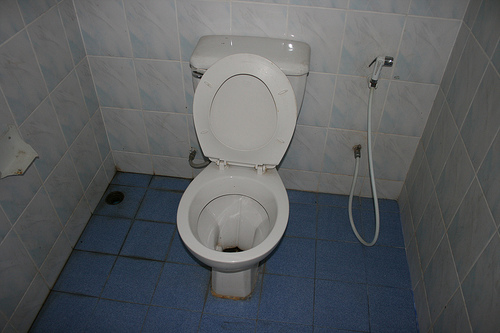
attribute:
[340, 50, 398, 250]
hose — white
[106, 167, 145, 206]
spot — brown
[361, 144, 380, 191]
ground — blue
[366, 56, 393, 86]
spray nozzle — white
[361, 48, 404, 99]
handle — black, a faucet handle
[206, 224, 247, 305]
spot — brown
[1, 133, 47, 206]
dispenser — broken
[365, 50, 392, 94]
faucet handle — black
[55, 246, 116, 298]
tile — blue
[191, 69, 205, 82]
handle — black, a faucet handle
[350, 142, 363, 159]
spot — brown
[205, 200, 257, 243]
bowl — from toilet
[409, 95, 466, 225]
wall — porcelain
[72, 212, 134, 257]
tile — blue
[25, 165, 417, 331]
floor —  tiled, blue 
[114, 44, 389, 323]
toilet. — white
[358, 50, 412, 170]
handle — a faucet handle, black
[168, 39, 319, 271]
toilet — white 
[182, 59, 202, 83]
flush handle — silver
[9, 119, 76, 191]
roll holder — white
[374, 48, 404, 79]
spout — silver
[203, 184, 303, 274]
interior — empty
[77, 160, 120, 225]
spot — brown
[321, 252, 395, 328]
tile — blur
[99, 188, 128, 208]
drain — small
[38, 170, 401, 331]
tile — blue